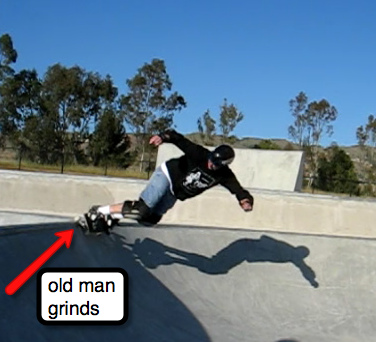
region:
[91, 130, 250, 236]
man on a skateboard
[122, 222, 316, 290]
shadow of a skateboarder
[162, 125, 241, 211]
black sweatshirt with white graphic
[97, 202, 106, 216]
white crew socks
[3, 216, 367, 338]
a cement skateboard ramp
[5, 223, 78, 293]
a red arrow points at skateboarder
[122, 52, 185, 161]
a tree beyond the fence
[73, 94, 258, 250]
man riding a skateboard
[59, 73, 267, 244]
man doing trick on skateboard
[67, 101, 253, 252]
man wearing black sweatshirt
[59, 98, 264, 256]
man wearing jean shorts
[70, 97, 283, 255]
man wearing knee pads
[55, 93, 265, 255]
man wearing white socks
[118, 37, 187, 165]
skinny tree with leaves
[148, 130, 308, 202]
small slab of concrete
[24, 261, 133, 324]
white sign with black words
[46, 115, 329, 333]
this is a skateboarder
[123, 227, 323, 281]
this is the skater's shadow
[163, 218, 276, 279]
the shadow is dark blue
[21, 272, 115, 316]
the text is black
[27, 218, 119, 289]
this is an arrow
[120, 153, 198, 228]
the man has knee pads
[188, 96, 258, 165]
this is a black helmet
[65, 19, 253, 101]
the sky is clear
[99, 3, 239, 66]
the sky is clear and blue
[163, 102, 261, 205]
the helmet is black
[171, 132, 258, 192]
the helmet is shiny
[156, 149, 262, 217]
the sweatshirt is black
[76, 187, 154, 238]
the man has knee pads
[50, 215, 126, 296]
the arrow is red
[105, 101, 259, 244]
a man is almost falling down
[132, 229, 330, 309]
the shadow of a man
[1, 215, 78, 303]
a red arrow pointing to a man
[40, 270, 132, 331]
this is a a sign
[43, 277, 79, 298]
a word on the sign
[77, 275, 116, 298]
a word on the sign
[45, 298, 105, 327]
a word on the sign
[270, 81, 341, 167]
this is a tree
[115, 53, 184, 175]
this is a tree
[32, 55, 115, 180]
this is a tree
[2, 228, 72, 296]
photo shop added red arrow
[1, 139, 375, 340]
poured concrete skate park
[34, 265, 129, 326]
photo shopped text box